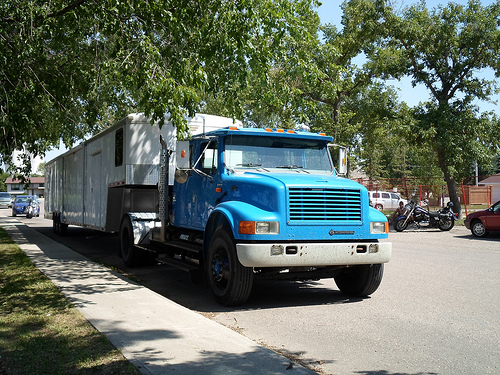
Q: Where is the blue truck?
A: On the street.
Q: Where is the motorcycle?
A: Parked on the side of the street.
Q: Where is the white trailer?
A: Attached to the blue truck.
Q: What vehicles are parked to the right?
A: Motorcycle and cars.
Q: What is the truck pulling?
A: A trailer.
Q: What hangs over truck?
A: Tree branches.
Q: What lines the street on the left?
A: A sidewalk.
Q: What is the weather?
A: Sunny.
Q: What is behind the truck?
A: A blue car.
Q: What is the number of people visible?
A: Zero.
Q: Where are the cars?
A: On pavement.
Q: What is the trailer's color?
A: White.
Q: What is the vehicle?
A: Truck.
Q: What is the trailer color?
A: White.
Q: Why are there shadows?
A: Sunny.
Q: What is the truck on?
A: Street.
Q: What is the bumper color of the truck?
A: White.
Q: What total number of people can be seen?
A: 0.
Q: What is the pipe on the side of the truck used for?
A: Exhaust.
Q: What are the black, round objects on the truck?
A: Tires.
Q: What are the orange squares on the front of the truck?
A: Lights.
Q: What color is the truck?
A: Blue.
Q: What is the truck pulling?
A: A trailer.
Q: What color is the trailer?
A: White.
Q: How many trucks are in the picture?
A: 1.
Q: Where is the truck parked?
A: In the street.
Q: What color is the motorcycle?
A: Black.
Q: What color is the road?
A: Gray.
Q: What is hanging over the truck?
A: A tree branch.